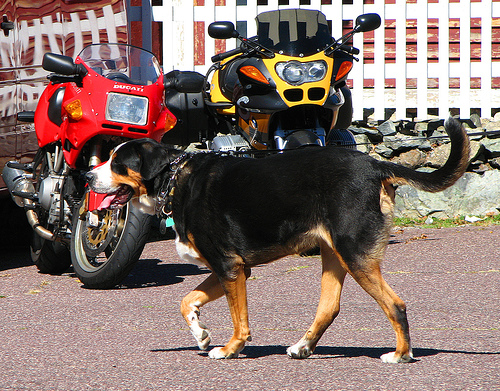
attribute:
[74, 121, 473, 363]
dog — brown, black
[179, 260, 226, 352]
leg — up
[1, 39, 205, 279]
surface — shiny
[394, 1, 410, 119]
post — wooden, white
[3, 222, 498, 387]
paved ground — grey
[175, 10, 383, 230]
motorcycle — big, yellow and black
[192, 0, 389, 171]
motorcycle — yellow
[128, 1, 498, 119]
fencing — white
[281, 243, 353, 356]
leg — brown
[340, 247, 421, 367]
leg — brown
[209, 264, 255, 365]
leg — brown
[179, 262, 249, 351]
leg — brown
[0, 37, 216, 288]
motorcycle — red, parked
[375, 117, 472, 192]
tail — brown and black, long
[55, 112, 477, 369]
dog — shiny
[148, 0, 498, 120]
fence — white, wooden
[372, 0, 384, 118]
post — wooden, white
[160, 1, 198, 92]
fence — white, wooden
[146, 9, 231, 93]
post — wooden, white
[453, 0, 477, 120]
post — white, wooden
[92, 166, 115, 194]
spot — white